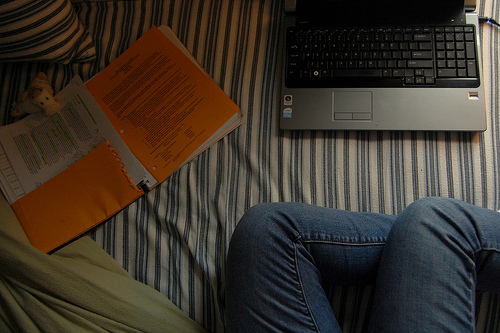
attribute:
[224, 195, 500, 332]
legs — bent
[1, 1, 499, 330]
sheet — striped, gray, white, brown, black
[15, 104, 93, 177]
text — highlighted, black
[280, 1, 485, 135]
laptop — silver, black, open, gray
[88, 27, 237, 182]
paper — orange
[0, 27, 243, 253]
folder — orange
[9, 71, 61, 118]
stuff cow — small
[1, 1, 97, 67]
pillow — striped, black, white, blue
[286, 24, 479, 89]
keyboard — black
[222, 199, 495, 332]
jeans — blue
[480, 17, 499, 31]
cable — black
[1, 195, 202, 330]
blanket — light green, pale green